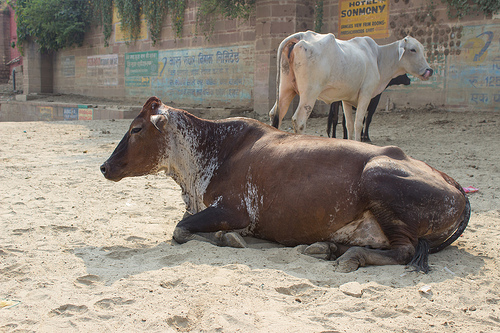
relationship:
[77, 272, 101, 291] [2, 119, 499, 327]
track on ground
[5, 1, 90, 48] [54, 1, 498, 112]
shrub on wall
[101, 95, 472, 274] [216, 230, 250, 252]
cow has a hoof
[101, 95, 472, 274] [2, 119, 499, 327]
cow on ground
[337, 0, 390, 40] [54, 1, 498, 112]
sign on wall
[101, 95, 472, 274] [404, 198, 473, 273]
cow has a tail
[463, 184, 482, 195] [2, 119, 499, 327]
trash on ground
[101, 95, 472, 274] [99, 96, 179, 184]
cow has a head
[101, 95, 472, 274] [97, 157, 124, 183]
cow has a nose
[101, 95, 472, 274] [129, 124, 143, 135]
cow has an eye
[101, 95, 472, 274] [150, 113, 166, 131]
cow has an ear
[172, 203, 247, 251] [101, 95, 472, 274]
leg of cow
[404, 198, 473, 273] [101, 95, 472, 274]
tail of cow